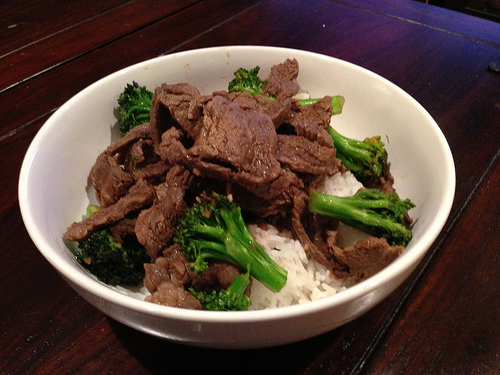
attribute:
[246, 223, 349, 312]
rice — white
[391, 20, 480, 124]
table — wood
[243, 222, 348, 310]
white rice — cooked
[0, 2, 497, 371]
table — shiny, brown, dark, wood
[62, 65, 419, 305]
food — healthy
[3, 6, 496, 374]
planks — stained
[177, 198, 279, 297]
broccoli — green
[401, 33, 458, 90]
table — dark colored, hardwood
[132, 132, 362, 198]
beef — succulent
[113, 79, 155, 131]
broccoli — green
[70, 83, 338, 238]
meat — well done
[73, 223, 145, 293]
broccoli — green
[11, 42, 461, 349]
bowl — white, ceramic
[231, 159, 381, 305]
rice — white, fluffy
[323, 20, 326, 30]
spot — small, white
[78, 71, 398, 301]
meal — healthy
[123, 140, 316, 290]
broccoli — green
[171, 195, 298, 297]
broccoli — green, cooked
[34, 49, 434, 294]
cermic bowl — white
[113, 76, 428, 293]
glass bowl — white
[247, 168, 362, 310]
rice — white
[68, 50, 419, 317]
meal — delicious, healthy, traditional Chinese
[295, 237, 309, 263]
rice — white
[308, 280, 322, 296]
rice — white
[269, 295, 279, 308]
rice — white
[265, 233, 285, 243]
rice — white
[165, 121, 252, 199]
slice — succulent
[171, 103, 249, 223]
slice — succulent